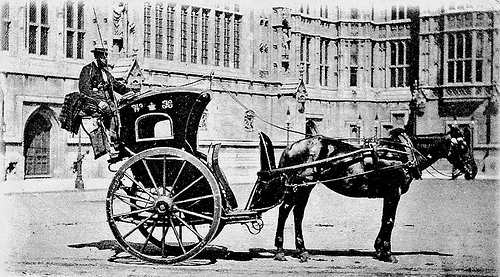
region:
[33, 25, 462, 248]
Black and white picture.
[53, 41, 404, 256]
One man is riding the horse carriage.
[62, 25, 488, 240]
Building is behind the horse.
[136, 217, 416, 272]
Shadow falls on ground.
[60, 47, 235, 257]
Two wheels for carriage.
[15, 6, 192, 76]
Windows are attached to the wall.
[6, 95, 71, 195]
Door is closed.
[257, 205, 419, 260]
Horse has four legs.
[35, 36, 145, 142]
Man is sitting behind the carriage.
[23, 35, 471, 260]
Day time picture.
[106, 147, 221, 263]
a large brown wagon wheel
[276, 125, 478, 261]
a large black horse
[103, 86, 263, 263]
a horse drawn wagon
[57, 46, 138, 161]
a man driving a wagon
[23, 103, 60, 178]
a large wooden door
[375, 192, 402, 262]
a horses front legs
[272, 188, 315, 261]
a horse's rear legs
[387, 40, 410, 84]
a window in a building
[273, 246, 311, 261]
a horse's rear hoofs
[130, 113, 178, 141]
window in a wagon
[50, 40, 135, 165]
A guy in picture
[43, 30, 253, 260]
A one person carriage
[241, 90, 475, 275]
A horse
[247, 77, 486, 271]
The horse is black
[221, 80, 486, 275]
Horse is on the ground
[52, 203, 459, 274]
This shadow is on the floor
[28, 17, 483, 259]
Photo is black and white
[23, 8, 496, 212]
Old buildings in the back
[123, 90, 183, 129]
Numbers on the carriage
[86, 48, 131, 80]
Smoking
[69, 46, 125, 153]
a man sitting on a carriage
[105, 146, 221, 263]
large wooden wheel on a carriage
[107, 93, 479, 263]
horse attached to a carriage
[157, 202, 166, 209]
bolt on a wheel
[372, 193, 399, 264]
a horse's front legs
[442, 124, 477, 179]
the head of a horse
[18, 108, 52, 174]
a large metal door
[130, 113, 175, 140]
a window on a carriage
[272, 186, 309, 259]
the back legs of a horse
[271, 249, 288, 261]
hoof of a horse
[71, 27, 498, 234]
a horse pulling a carriage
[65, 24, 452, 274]
a horse and carriage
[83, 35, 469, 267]
a horse pulling a small carriage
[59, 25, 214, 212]
a man sitting on the carriage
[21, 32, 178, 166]
a man sitting on the back of the carriage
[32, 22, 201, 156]
a man wearing a hat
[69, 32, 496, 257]
a horse harnessed to a carriage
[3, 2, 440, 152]
a very old building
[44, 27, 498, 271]
a horse and carriage outside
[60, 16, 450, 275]
a carriage and horse standing outside